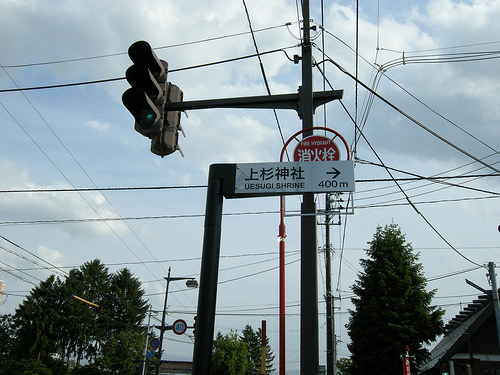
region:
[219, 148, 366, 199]
this is a sign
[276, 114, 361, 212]
this is a sign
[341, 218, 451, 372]
this is a tree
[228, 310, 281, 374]
this is a tree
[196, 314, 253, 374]
this is a tree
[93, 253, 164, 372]
this is a tree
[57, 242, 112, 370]
this is a tree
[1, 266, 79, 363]
this is a tree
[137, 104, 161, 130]
green light is shining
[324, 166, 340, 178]
a black arrow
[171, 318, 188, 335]
number forty on the metal sign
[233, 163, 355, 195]
a white street sign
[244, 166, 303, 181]
Asian text on the sign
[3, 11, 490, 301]
sky is full of electrical lines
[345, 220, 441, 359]
an evergreen tree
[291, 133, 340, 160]
a round red sign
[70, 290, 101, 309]
yellow electrical guard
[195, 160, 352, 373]
street sign on a black post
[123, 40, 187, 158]
A traffic light.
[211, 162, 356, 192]
A street sign.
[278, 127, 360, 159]
A street sign.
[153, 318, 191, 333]
A speed sign.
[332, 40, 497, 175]
A lot of electrical cables.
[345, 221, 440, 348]
A big full tree.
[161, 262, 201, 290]
A street light stands over the street.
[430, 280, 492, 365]
A roof of a building.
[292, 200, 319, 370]
A street pole in between other poles.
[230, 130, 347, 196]
black and white sign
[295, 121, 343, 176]
red and white sign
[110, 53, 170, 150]
green traffic light on pole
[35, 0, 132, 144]
grey and blue sky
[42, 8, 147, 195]
thick grey clouds in sky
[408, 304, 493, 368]
small building near trees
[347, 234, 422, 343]
tall and green trees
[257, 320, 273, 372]
black and yellow pole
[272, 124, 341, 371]
sign on orange pole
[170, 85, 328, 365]
traffic light on black pole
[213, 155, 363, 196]
a white street sign on a green pole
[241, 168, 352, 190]
words on the street sign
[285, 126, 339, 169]
a red circle sign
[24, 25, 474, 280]
wires above the street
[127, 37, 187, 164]
a green street light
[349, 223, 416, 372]
a tree next to a building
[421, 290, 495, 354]
a building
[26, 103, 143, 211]
clouds in the sky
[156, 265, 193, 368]
a street light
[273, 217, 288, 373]
a red pole